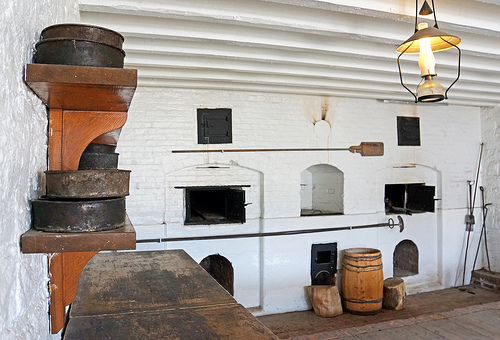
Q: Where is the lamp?
A: Hanging from the ceiling.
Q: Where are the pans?
A: On the shelving to the left.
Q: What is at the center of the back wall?
A: A barrel.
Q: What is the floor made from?
A: Wood.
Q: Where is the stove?
A: On the back wall.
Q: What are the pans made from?
A: Metal.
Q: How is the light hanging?
A: From a hook.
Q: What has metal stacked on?
A: Shelves.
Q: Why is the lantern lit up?
A: It's on.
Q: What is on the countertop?
A: There is nothing on the counter top.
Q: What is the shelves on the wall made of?
A: Wood.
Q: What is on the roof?
A: Wood beams.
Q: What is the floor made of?
A: Bricks.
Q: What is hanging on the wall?
A: A peel.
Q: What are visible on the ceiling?
A: White painted beams.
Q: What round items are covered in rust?
A: Large baking pans.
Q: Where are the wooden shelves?
A: Anchored to wall.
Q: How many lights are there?
A: One.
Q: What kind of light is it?
A: A lantern.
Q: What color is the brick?
A: White.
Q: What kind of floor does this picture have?
A: Wood floor.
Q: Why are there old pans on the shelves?
A: They are old cooking pots and pans.